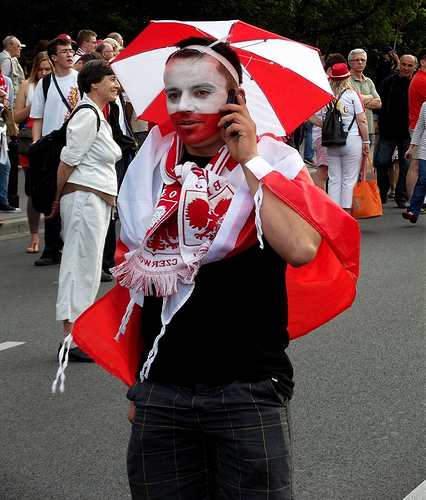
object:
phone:
[225, 86, 241, 130]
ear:
[233, 83, 247, 103]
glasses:
[58, 45, 78, 57]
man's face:
[56, 42, 76, 71]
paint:
[160, 58, 230, 116]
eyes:
[166, 85, 185, 101]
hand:
[215, 87, 259, 159]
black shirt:
[135, 140, 292, 397]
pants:
[126, 379, 296, 500]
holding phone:
[217, 77, 257, 166]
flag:
[50, 124, 362, 399]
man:
[342, 45, 383, 170]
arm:
[354, 76, 381, 109]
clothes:
[55, 95, 122, 324]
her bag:
[319, 87, 357, 151]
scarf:
[108, 119, 238, 299]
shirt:
[127, 153, 293, 396]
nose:
[174, 92, 192, 116]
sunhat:
[104, 17, 338, 140]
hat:
[325, 63, 354, 83]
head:
[328, 68, 350, 92]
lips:
[176, 121, 201, 130]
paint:
[173, 113, 208, 146]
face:
[159, 52, 225, 141]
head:
[157, 39, 245, 150]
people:
[0, 33, 27, 210]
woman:
[53, 55, 121, 364]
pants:
[56, 187, 110, 321]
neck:
[186, 141, 226, 158]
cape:
[69, 123, 359, 386]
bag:
[350, 145, 383, 217]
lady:
[319, 63, 371, 216]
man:
[49, 34, 362, 500]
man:
[28, 36, 80, 253]